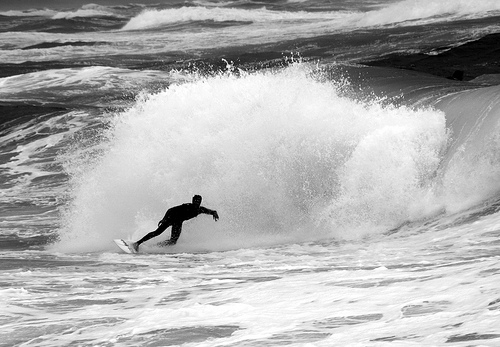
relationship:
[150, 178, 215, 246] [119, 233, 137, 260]
man on surboard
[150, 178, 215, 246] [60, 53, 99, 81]
man in water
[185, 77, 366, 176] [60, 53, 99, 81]
waves in water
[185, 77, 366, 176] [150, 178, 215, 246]
waves near man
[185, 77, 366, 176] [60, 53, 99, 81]
waves on water